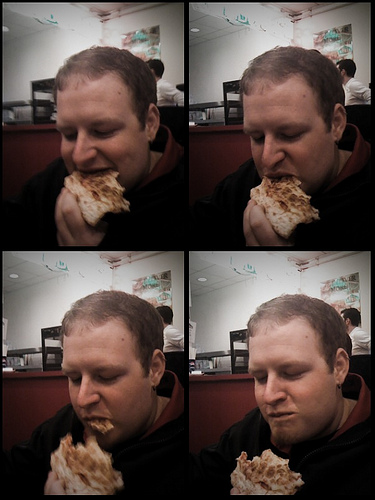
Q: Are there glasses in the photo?
A: No, there are no glasses.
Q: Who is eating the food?
A: The man is eating the food.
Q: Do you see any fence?
A: No, there are no fences.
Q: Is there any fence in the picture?
A: No, there are no fences.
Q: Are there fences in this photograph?
A: No, there are no fences.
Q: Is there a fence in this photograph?
A: No, there are no fences.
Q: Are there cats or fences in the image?
A: No, there are no fences or cats.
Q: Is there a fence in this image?
A: No, there are no fences.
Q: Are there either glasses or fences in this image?
A: No, there are no fences or glasses.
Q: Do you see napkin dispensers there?
A: No, there are no napkin dispensers.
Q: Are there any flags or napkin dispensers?
A: No, there are no napkin dispensers or flags.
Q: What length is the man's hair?
A: The hair is short.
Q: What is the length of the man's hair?
A: The hair is short.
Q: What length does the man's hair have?
A: The hair has short length.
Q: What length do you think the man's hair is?
A: The hair is short.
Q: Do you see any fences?
A: No, there are no fences.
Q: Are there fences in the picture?
A: No, there are no fences.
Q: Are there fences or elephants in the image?
A: No, there are no fences or elephants.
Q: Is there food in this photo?
A: Yes, there is food.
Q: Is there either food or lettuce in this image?
A: Yes, there is food.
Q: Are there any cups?
A: No, there are no cups.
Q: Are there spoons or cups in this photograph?
A: No, there are no cups or spoons.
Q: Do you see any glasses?
A: No, there are no glasses.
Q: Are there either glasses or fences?
A: No, there are no glasses or fences.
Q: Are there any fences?
A: No, there are no fences.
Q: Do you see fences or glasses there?
A: No, there are no fences or glasses.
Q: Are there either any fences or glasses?
A: No, there are no fences or glasses.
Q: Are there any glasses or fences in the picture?
A: No, there are no fences or glasses.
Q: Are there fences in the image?
A: No, there are no fences.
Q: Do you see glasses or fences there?
A: No, there are no fences or glasses.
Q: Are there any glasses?
A: No, there are no glasses.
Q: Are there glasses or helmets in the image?
A: No, there are no glasses or helmets.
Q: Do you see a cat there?
A: No, there are no cats.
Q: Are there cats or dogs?
A: No, there are no cats or dogs.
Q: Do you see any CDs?
A: No, there are no cds.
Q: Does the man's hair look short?
A: Yes, the hair is short.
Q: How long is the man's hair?
A: The hair is short.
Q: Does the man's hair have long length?
A: No, the hair is short.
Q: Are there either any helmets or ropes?
A: No, there are no helmets or ropes.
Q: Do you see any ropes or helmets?
A: No, there are no helmets or ropes.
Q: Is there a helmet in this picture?
A: No, there are no helmets.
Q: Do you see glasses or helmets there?
A: No, there are no helmets or glasses.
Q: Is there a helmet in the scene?
A: No, there are no helmets.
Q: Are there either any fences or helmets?
A: No, there are no helmets or fences.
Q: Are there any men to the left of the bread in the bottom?
A: Yes, there is a man to the left of the bread.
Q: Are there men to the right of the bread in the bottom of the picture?
A: No, the man is to the left of the bread.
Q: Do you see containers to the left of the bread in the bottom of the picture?
A: No, there is a man to the left of the bread.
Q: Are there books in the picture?
A: No, there are no books.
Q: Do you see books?
A: No, there are no books.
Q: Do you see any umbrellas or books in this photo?
A: No, there are no books or umbrellas.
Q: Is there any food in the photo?
A: Yes, there is food.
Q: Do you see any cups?
A: No, there are no cups.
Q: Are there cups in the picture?
A: No, there are no cups.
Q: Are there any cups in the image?
A: No, there are no cups.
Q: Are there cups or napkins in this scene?
A: No, there are no cups or napkins.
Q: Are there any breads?
A: Yes, there is a bread.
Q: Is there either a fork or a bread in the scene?
A: Yes, there is a bread.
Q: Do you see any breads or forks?
A: Yes, there is a bread.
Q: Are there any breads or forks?
A: Yes, there is a bread.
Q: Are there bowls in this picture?
A: No, there are no bowls.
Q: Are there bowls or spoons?
A: No, there are no bowls or spoons.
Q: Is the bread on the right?
A: Yes, the bread is on the right of the image.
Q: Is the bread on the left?
A: No, the bread is on the right of the image.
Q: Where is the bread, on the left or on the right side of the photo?
A: The bread is on the right of the image.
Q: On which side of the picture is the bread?
A: The bread is on the right of the image.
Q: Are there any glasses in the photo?
A: No, there are no glasses.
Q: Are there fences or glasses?
A: No, there are no glasses or fences.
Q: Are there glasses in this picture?
A: No, there are no glasses.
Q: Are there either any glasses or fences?
A: No, there are no glasses or fences.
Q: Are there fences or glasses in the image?
A: No, there are no glasses or fences.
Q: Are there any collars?
A: Yes, there is a collar.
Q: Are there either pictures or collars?
A: Yes, there is a collar.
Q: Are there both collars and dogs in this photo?
A: No, there is a collar but no dogs.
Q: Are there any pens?
A: No, there are no pens.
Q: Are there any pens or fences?
A: No, there are no pens or fences.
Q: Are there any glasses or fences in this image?
A: No, there are no fences or glasses.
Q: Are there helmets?
A: No, there are no helmets.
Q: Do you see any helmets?
A: No, there are no helmets.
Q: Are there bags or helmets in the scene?
A: No, there are no helmets or bags.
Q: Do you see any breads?
A: Yes, there is a bread.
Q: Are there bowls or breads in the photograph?
A: Yes, there is a bread.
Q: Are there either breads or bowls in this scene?
A: Yes, there is a bread.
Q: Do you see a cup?
A: No, there are no cups.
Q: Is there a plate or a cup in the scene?
A: No, there are no cups or plates.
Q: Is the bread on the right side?
A: Yes, the bread is on the right of the image.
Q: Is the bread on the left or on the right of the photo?
A: The bread is on the right of the image.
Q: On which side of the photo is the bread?
A: The bread is on the right of the image.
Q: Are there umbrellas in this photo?
A: No, there are no umbrellas.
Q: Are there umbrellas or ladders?
A: No, there are no umbrellas or ladders.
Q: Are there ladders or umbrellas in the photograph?
A: No, there are no umbrellas or ladders.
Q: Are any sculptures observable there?
A: No, there are no sculptures.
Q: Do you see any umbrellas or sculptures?
A: No, there are no sculptures or umbrellas.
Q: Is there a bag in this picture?
A: No, there are no bags.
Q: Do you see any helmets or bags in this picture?
A: No, there are no bags or helmets.